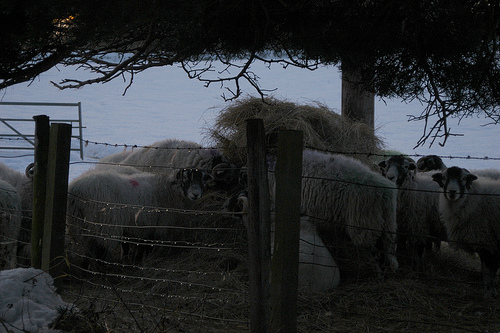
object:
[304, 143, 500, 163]
wire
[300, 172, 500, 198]
wire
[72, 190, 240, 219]
wire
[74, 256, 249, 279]
wire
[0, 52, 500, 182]
snow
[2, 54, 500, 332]
ground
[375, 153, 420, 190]
head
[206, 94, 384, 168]
straw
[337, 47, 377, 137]
post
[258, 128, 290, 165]
hair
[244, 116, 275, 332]
post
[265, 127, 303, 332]
post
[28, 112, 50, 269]
post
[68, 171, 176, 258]
white body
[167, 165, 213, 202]
black head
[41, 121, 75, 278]
post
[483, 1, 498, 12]
leaves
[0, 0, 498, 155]
tree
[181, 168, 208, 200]
face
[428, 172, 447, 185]
ears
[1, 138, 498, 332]
sheep herd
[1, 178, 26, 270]
sheep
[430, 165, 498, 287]
sheep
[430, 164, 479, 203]
head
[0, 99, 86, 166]
gate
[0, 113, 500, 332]
fence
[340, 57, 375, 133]
trunk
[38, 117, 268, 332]
wire fence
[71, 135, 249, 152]
wires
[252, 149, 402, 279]
body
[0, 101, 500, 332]
pen